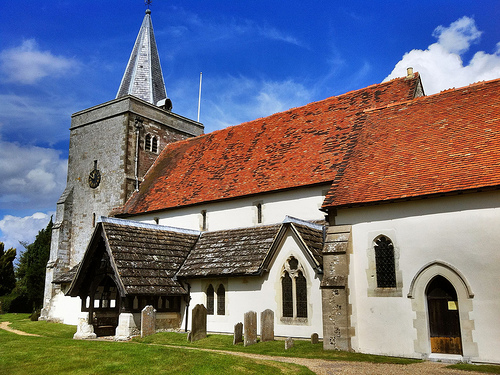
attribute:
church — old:
[48, 6, 498, 358]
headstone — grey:
[235, 322, 243, 344]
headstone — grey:
[244, 312, 259, 346]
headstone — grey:
[261, 307, 274, 341]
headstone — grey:
[283, 335, 295, 350]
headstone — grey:
[309, 332, 320, 346]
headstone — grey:
[189, 305, 210, 342]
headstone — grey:
[140, 305, 157, 340]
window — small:
[255, 206, 261, 221]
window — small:
[199, 210, 205, 228]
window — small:
[154, 219, 159, 224]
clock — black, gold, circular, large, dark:
[85, 160, 103, 192]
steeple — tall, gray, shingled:
[112, 0, 174, 110]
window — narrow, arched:
[374, 238, 396, 289]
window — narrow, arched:
[292, 272, 309, 316]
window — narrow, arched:
[277, 274, 292, 315]